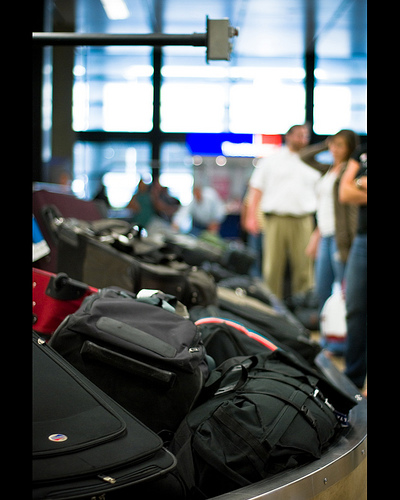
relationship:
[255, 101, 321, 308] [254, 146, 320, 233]
man wearing shirt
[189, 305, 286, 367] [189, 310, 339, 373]
stripe on bag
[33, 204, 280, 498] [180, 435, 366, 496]
bags on rack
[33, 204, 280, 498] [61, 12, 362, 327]
bags in airport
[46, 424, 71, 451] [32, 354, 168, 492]
decal on suitcase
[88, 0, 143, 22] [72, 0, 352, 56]
light on ceiling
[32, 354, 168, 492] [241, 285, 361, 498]
suitcase on mat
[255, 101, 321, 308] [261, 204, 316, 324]
man wearing pants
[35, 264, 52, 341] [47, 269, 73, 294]
luggage has wheels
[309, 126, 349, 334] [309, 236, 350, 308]
woman wearing jeans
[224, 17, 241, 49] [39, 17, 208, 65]
button on pole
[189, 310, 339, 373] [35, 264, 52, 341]
backpack on luggage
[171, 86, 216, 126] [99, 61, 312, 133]
light through windows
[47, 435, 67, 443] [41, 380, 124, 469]
button on luggage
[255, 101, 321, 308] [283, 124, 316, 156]
man has head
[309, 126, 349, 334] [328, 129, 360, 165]
woman has head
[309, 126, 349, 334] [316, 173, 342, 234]
woman has shirt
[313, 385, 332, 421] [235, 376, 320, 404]
metal on belt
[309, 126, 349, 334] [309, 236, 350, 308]
woman has jeans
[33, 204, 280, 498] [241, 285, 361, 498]
luggage on conveyor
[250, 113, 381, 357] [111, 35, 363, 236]
people in background